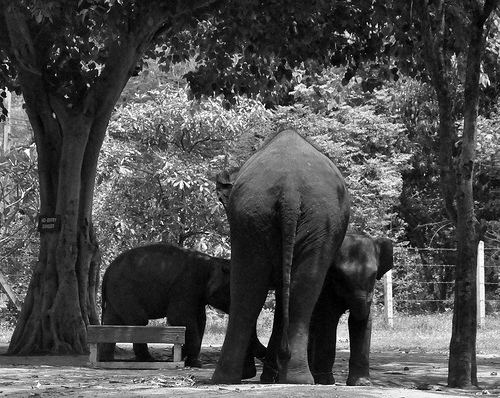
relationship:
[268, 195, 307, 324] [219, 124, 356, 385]
tail of elephant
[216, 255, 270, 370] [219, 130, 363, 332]
left leg of elephant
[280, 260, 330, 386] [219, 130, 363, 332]
leg of elephant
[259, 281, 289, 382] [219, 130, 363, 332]
leg of elephant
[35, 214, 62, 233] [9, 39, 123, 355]
sign on tree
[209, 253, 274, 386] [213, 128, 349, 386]
left leg of elephant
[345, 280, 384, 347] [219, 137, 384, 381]
trunk of elephant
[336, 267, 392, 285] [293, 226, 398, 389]
eyes of elephant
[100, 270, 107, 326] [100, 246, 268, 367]
tail of elephant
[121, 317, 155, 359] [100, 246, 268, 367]
leg of elephant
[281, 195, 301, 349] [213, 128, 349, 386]
tail of elephant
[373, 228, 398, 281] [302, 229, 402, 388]
ear of elephant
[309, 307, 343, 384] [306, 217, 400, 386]
leg of lelephant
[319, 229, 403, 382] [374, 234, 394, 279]
elephant has ear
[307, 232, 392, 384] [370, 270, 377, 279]
elephant has eye